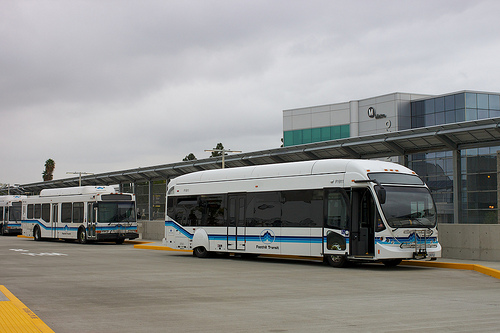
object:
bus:
[162, 158, 445, 269]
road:
[55, 234, 235, 311]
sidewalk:
[142, 241, 164, 252]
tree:
[42, 158, 57, 181]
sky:
[123, 27, 242, 150]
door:
[347, 185, 378, 260]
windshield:
[374, 186, 437, 229]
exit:
[226, 192, 247, 251]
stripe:
[207, 231, 350, 244]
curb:
[444, 256, 499, 281]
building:
[286, 91, 491, 147]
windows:
[416, 115, 426, 126]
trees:
[209, 142, 229, 158]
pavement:
[6, 244, 69, 260]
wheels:
[323, 235, 348, 267]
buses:
[20, 183, 141, 241]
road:
[0, 238, 69, 332]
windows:
[246, 195, 321, 226]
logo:
[255, 229, 280, 250]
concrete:
[206, 269, 459, 325]